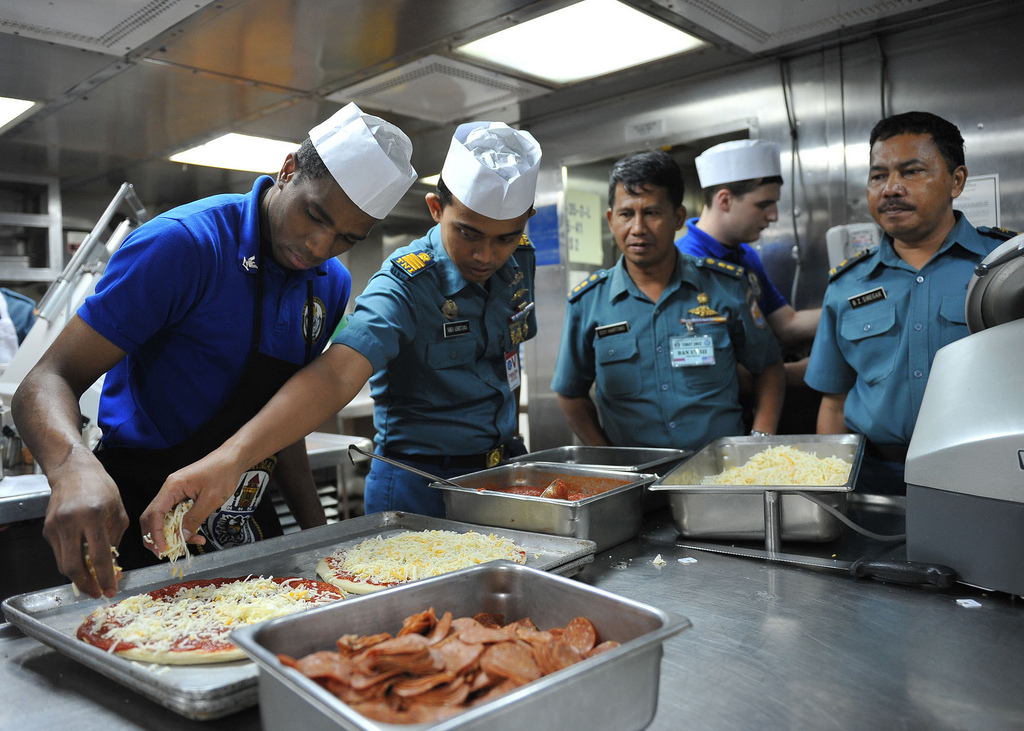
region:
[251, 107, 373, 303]
the head of a man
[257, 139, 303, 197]
the ear of a man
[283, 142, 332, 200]
the hair of a man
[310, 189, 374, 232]
the forehead of a man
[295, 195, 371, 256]
the eye of a man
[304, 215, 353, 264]
the nose of a man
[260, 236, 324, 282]
the mouth of a man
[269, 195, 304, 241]
the cheek of a man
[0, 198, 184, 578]
the arm of a man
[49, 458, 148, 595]
the hand of a man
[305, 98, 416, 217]
person has a hat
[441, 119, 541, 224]
person has a hat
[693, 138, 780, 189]
person has a hat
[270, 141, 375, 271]
person has a head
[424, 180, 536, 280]
person has a head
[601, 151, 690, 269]
person has a head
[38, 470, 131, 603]
person has a hand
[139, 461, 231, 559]
person has a hand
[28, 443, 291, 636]
they are putting cheese on the pizza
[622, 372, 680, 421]
his shirt is teal in color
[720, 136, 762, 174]
the hat on his head is white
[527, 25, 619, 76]
the light is turned on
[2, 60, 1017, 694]
these are a group of men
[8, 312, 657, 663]
these are pizzas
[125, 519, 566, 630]
the pizza has mozzarella cheese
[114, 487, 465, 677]
the cheese is white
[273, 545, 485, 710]
the meat is pepperoni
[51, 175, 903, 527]
the men are military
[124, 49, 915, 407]
the men are in uniform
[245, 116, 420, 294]
the nose of a man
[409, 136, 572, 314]
the face of a man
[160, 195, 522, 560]
the arm of a man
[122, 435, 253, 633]
the hand of a man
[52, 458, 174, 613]
the fingers of a man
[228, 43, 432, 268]
a man wearing a hat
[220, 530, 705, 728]
metal tub full of food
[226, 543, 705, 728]
metal tub full of food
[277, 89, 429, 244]
white hat worn by man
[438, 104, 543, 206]
white hat worn by man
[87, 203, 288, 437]
blue shirt worn by man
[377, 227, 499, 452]
blue shirt worn by man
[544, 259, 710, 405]
blue shirt worn by man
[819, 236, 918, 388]
blue shirt worn by man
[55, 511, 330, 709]
pizza being cooked by man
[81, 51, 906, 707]
people preparing food in the kitchen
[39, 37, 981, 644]
a restaurant kitchen in the background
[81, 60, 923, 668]
people wearing hats in the kitchen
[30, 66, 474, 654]
person wearing a white hat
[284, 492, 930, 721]
pepperoni in the bowl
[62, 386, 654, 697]
cheese on the pizza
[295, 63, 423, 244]
white hat worn by man